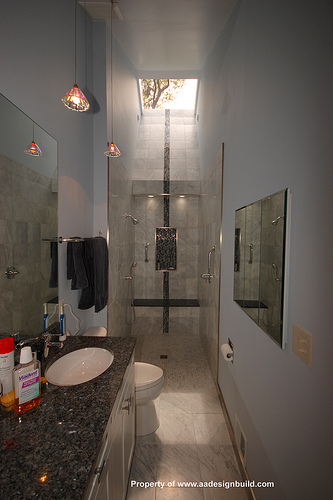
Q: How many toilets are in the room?
A: One.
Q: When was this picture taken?
A: Daytime.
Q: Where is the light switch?
A: On the right wall.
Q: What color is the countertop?
A: Dark gray.